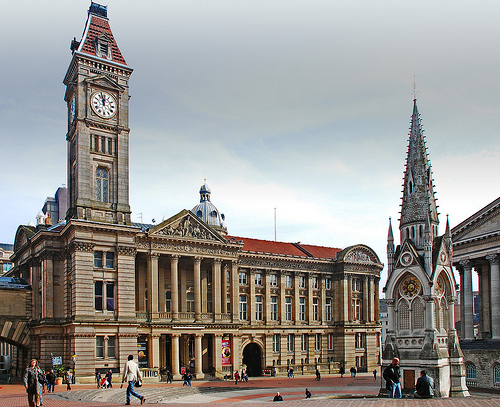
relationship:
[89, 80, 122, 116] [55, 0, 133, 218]
clock on tower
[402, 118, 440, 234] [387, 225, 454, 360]
steeple on building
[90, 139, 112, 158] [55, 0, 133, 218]
windows are on tower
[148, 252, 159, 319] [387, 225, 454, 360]
columns are on building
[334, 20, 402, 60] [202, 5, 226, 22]
clouds are in sky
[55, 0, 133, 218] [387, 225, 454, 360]
tower on top of building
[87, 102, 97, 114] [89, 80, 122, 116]
numerals are on clock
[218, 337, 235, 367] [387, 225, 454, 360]
banner hanging on building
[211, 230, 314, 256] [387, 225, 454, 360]
roof on building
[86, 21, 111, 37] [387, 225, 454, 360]
vent on building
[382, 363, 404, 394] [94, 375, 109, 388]
person pushing stroller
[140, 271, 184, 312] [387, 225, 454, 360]
columns are on building